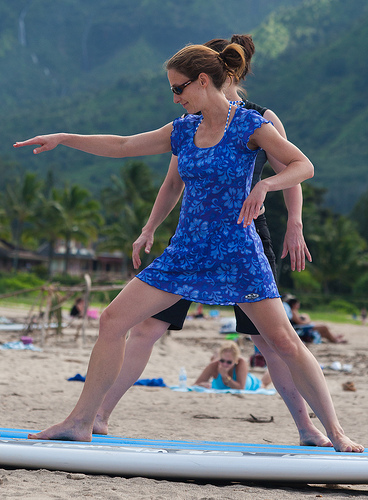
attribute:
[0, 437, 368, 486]
surfboard — white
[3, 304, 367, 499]
sand — beach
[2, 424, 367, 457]
surfboard — blue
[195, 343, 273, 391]
woman — relaxing, lying down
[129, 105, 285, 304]
dress — blue, blue floral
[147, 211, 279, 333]
shorts — black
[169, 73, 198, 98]
glasses — dark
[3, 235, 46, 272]
house — distant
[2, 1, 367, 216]
mountain — distant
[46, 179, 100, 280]
palm tree — distant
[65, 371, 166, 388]
towel — blue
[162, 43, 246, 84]
hair — bun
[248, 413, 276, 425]
pipe — edge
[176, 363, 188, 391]
bottle — water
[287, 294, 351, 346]
person — sitting